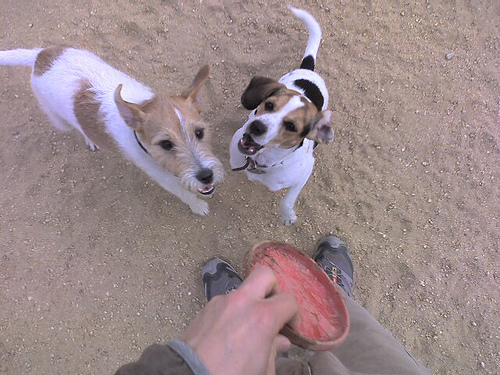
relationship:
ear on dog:
[177, 62, 217, 117] [55, 37, 252, 204]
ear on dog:
[239, 72, 284, 109] [222, 7, 360, 227]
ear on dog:
[305, 105, 337, 149] [222, 7, 360, 227]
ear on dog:
[108, 75, 144, 132] [0, 39, 222, 215]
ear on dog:
[177, 62, 217, 117] [0, 39, 222, 215]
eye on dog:
[154, 138, 173, 150] [14, 38, 236, 216]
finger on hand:
[239, 257, 277, 296] [175, 260, 299, 373]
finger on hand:
[267, 290, 305, 325] [175, 260, 299, 373]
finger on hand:
[266, 330, 299, 371] [175, 260, 299, 373]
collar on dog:
[232, 156, 269, 176] [228, 2, 333, 227]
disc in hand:
[233, 234, 355, 350] [181, 262, 303, 372]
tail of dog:
[282, 2, 325, 72] [226, 2, 343, 227]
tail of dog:
[0, 42, 40, 68] [0, 39, 222, 215]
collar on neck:
[236, 157, 305, 176] [264, 142, 306, 173]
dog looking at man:
[0, 39, 222, 215] [98, 231, 439, 373]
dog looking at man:
[226, 2, 343, 227] [98, 231, 439, 373]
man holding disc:
[98, 231, 439, 373] [233, 230, 355, 350]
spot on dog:
[74, 78, 124, 160] [0, 39, 222, 215]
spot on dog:
[33, 45, 74, 77] [0, 39, 222, 215]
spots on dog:
[295, 49, 336, 113] [226, 2, 343, 227]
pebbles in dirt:
[428, 35, 463, 76] [408, 98, 492, 283]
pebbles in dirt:
[377, 220, 390, 247] [359, 112, 466, 204]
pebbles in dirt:
[82, 247, 122, 303] [2, 0, 494, 371]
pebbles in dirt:
[34, 187, 170, 300] [30, 201, 145, 293]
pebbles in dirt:
[382, 35, 476, 118] [410, 179, 449, 290]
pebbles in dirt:
[40, 250, 122, 295] [19, 160, 145, 338]